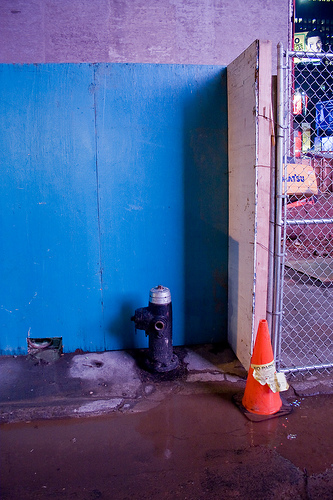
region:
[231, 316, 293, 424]
Orange cone on the ground.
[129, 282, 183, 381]
Fire hydrant by the building.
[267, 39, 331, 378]
chain link fence in the background.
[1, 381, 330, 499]
Water on the ground.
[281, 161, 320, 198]
box behind the fence.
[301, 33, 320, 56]
Face on the sign.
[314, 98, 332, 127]
Blue sign in the background.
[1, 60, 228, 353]
Blue wall on the building.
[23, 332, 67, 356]
Hole in the wall.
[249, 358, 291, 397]
Sticker on the cone.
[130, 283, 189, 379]
navy blue fire hydrant with a silver top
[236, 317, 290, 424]
orange plastic safety cone with a torn white paper attached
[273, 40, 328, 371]
portion of chain link fencing attached to a partial wall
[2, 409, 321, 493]
wet brown pavement near fire hydrant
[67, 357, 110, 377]
found hole in gray pavement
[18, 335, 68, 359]
rectanglular hole in a blue wall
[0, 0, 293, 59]
gray wall above a blue wall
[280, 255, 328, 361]
cement paving blocks behind a fence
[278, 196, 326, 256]
dirt in a construction area behind a fence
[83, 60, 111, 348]
seam in a blue painted wall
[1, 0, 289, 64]
gray cement wall over blue painted wall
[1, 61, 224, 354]
blue painted wall made of plywood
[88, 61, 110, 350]
seam between two pieces of blue plywood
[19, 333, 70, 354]
rectangle cut out of blue plywood on wall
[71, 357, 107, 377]
round hold in gray cement paving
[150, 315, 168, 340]
open nozzle on navy blue fire hydrant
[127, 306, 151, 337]
nozzle on navy blue fire hydrant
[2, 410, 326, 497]
went brown cement pavement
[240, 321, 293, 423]
orange plastic safety cone with torn paper attached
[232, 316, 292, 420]
An orange caution cone.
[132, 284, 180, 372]
A black fire hydrant with silver top.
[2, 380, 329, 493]
All of the wet brown floor.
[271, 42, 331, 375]
A chain link silver fence.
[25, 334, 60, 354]
A hole in the blue wall.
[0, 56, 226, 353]
A bright blue wall.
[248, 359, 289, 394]
A ripped note on the caution cone.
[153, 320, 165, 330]
Open black hole on the fire hydrant.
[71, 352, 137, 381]
Dry concrete to the left of a hydrant.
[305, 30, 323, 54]
A man's face on a sign past the fence.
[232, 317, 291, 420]
an orange traffic cone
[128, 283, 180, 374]
a decaying fire hydrant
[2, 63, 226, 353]
a tall blue wall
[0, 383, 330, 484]
a dirty puddle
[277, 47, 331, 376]
a chain link fence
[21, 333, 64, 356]
a gap in a wall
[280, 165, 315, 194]
a yellow construction vehicle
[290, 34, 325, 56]
a billboard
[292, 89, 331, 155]
bright signs and lights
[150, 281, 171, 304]
a metal top of a fire hydrant